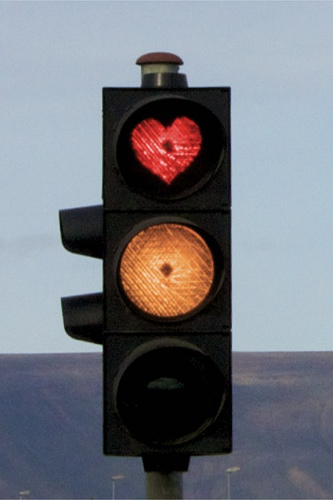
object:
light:
[60, 47, 234, 470]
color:
[136, 237, 198, 306]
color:
[144, 382, 190, 423]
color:
[149, 128, 185, 174]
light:
[111, 333, 225, 448]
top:
[97, 74, 235, 112]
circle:
[112, 96, 227, 197]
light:
[105, 88, 233, 209]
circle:
[111, 214, 227, 324]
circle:
[113, 339, 224, 446]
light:
[114, 95, 224, 200]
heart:
[131, 116, 201, 186]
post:
[142, 462, 188, 498]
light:
[224, 462, 246, 500]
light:
[110, 471, 126, 497]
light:
[18, 488, 31, 498]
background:
[0, 0, 333, 496]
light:
[118, 214, 222, 323]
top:
[136, 44, 194, 86]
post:
[137, 49, 186, 500]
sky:
[0, 0, 333, 353]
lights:
[58, 204, 114, 295]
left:
[20, 76, 125, 498]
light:
[89, 82, 238, 204]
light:
[53, 78, 235, 469]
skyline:
[233, 337, 326, 373]